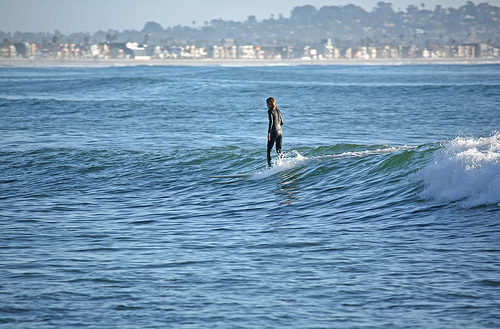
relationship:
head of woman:
[266, 97, 277, 107] [266, 97, 285, 168]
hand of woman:
[267, 132, 273, 142] [266, 97, 285, 168]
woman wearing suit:
[266, 97, 285, 168] [267, 106, 283, 166]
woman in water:
[266, 97, 285, 168] [1, 66, 499, 329]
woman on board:
[266, 97, 285, 168] [212, 173, 260, 181]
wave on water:
[283, 140, 499, 208] [1, 66, 499, 329]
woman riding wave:
[266, 97, 285, 168] [283, 140, 499, 208]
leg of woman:
[264, 142, 275, 166] [266, 97, 285, 168]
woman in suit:
[266, 97, 285, 168] [267, 106, 283, 166]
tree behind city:
[248, 17, 258, 47] [5, 39, 499, 60]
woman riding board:
[266, 97, 285, 168] [212, 173, 260, 181]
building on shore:
[9, 47, 19, 58] [6, 58, 499, 65]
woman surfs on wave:
[266, 97, 285, 168] [283, 140, 499, 208]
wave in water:
[283, 140, 499, 208] [1, 66, 499, 329]